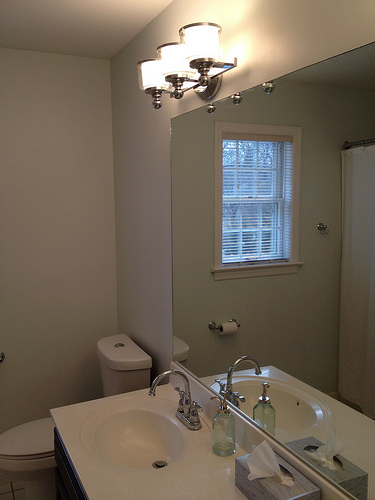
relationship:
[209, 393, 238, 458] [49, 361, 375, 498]
bottle on sink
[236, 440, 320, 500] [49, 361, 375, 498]
tissue box on sink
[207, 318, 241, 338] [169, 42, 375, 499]
toilet paper in mirror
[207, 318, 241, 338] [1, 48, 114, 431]
toilet paper on wall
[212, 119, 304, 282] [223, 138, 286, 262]
window has mini blinds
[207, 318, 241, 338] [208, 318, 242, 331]
toilet paper has holder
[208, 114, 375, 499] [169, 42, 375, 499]
reflection in mirror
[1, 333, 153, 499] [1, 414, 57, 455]
toilet has toilet seat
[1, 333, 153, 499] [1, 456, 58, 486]
toilet has bowl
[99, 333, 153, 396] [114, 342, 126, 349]
toilet tank has push button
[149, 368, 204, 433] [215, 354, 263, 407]
faucet has reflection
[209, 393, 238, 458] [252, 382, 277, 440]
bottle has reflection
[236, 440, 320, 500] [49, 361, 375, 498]
tissue box on top of sink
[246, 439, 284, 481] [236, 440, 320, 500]
tissue in tissue box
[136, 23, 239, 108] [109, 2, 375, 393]
lights are fixed to wall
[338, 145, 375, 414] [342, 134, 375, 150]
shower curtain on rod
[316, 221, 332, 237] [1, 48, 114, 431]
wall hook on wall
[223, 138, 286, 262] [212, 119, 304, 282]
mini blinds are on window